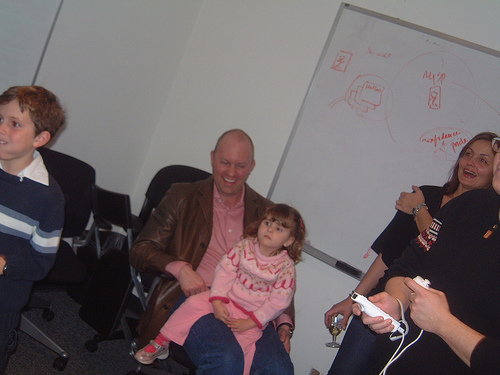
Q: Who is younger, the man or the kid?
A: The kid is younger than the man.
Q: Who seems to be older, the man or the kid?
A: The man is older than the kid.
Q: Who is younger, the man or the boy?
A: The boy is younger than the man.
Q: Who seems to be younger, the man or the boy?
A: The boy is younger than the man.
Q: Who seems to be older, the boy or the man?
A: The man is older than the boy.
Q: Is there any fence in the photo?
A: No, there are no fences.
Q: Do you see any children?
A: Yes, there is a child.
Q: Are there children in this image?
A: Yes, there is a child.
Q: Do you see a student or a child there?
A: Yes, there is a child.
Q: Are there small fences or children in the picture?
A: Yes, there is a small child.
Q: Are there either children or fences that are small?
A: Yes, the child is small.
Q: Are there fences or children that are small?
A: Yes, the child is small.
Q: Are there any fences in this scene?
A: No, there are no fences.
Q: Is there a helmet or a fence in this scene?
A: No, there are no fences or helmets.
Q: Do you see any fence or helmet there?
A: No, there are no fences or helmets.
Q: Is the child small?
A: Yes, the child is small.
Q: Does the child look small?
A: Yes, the child is small.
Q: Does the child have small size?
A: Yes, the child is small.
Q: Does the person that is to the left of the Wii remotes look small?
A: Yes, the child is small.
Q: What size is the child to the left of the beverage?
A: The child is small.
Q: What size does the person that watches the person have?
A: The child has small size.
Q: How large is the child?
A: The child is small.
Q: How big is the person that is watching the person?
A: The child is small.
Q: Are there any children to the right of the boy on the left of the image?
A: Yes, there is a child to the right of the boy.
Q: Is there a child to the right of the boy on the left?
A: Yes, there is a child to the right of the boy.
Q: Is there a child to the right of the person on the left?
A: Yes, there is a child to the right of the boy.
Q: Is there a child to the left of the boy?
A: No, the child is to the right of the boy.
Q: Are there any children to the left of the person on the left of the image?
A: No, the child is to the right of the boy.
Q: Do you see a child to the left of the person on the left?
A: No, the child is to the right of the boy.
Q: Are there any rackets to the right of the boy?
A: No, there is a child to the right of the boy.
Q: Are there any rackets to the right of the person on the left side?
A: No, there is a child to the right of the boy.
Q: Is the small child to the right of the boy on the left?
A: Yes, the kid is to the right of the boy.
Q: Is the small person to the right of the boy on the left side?
A: Yes, the kid is to the right of the boy.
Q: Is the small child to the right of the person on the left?
A: Yes, the kid is to the right of the boy.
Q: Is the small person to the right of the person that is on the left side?
A: Yes, the kid is to the right of the boy.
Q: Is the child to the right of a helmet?
A: No, the child is to the right of the boy.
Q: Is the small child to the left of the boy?
A: No, the child is to the right of the boy.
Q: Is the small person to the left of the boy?
A: No, the child is to the right of the boy.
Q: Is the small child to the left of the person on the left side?
A: No, the child is to the right of the boy.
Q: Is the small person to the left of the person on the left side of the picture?
A: No, the child is to the right of the boy.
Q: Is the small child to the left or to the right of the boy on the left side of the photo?
A: The child is to the right of the boy.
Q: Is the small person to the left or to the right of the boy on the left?
A: The child is to the right of the boy.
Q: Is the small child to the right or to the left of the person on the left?
A: The child is to the right of the boy.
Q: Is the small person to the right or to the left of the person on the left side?
A: The child is to the right of the boy.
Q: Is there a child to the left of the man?
A: Yes, there is a child to the left of the man.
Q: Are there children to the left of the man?
A: Yes, there is a child to the left of the man.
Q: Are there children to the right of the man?
A: No, the child is to the left of the man.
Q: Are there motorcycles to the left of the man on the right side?
A: No, there is a child to the left of the man.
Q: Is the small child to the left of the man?
A: Yes, the child is to the left of the man.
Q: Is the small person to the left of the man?
A: Yes, the child is to the left of the man.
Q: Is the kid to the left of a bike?
A: No, the kid is to the left of the man.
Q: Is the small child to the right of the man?
A: No, the child is to the left of the man.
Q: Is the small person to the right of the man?
A: No, the child is to the left of the man.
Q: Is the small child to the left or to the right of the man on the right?
A: The child is to the left of the man.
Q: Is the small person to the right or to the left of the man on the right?
A: The child is to the left of the man.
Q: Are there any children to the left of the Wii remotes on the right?
A: Yes, there is a child to the left of the Wii remotes.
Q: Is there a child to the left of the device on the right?
A: Yes, there is a child to the left of the Wii remotes.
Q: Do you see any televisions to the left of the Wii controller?
A: No, there is a child to the left of the Wii controller.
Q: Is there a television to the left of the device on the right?
A: No, there is a child to the left of the Wii controller.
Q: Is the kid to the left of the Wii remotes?
A: Yes, the kid is to the left of the Wii remotes.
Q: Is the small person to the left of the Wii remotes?
A: Yes, the kid is to the left of the Wii remotes.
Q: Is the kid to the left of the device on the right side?
A: Yes, the kid is to the left of the Wii remotes.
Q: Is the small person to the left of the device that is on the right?
A: Yes, the kid is to the left of the Wii remotes.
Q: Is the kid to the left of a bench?
A: No, the kid is to the left of the Wii remotes.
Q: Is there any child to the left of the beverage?
A: Yes, there is a child to the left of the beverage.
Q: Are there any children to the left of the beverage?
A: Yes, there is a child to the left of the beverage.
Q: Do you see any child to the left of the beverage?
A: Yes, there is a child to the left of the beverage.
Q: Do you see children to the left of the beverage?
A: Yes, there is a child to the left of the beverage.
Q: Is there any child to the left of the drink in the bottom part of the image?
A: Yes, there is a child to the left of the beverage.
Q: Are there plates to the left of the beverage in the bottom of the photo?
A: No, there is a child to the left of the beverage.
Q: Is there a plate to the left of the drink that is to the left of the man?
A: No, there is a child to the left of the beverage.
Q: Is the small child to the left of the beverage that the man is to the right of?
A: Yes, the kid is to the left of the beverage.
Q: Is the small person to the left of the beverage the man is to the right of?
A: Yes, the kid is to the left of the beverage.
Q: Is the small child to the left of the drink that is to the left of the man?
A: Yes, the kid is to the left of the beverage.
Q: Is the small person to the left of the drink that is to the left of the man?
A: Yes, the kid is to the left of the beverage.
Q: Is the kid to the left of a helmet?
A: No, the kid is to the left of the beverage.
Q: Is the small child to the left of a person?
A: Yes, the child is to the left of a person.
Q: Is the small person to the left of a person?
A: Yes, the child is to the left of a person.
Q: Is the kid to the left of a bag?
A: No, the kid is to the left of a person.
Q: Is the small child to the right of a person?
A: No, the kid is to the left of a person.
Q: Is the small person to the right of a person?
A: No, the kid is to the left of a person.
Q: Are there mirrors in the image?
A: No, there are no mirrors.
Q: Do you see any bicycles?
A: No, there are no bicycles.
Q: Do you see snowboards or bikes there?
A: No, there are no bikes or snowboards.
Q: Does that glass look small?
A: Yes, the glass is small.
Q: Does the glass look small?
A: Yes, the glass is small.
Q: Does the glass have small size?
A: Yes, the glass is small.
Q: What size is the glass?
A: The glass is small.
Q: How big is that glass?
A: The glass is small.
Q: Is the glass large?
A: No, the glass is small.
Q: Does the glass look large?
A: No, the glass is small.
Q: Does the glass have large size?
A: No, the glass is small.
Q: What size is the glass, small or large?
A: The glass is small.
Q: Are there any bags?
A: No, there are no bags.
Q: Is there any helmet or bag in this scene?
A: No, there are no bags or helmets.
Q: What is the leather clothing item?
A: The clothing item is a jacket.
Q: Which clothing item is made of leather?
A: The clothing item is a jacket.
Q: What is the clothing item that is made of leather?
A: The clothing item is a jacket.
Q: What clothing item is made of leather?
A: The clothing item is a jacket.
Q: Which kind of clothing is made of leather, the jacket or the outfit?
A: The jacket is made of leather.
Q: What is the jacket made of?
A: The jacket is made of leather.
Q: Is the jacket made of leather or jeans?
A: The jacket is made of leather.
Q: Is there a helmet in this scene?
A: No, there are no helmets.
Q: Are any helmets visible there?
A: No, there are no helmets.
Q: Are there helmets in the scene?
A: No, there are no helmets.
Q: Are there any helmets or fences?
A: No, there are no helmets or fences.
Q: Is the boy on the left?
A: Yes, the boy is on the left of the image.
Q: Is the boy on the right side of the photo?
A: No, the boy is on the left of the image.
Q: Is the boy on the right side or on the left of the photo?
A: The boy is on the left of the image.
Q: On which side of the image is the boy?
A: The boy is on the left of the image.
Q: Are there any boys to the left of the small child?
A: Yes, there is a boy to the left of the child.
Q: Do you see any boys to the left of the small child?
A: Yes, there is a boy to the left of the child.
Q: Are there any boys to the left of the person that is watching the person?
A: Yes, there is a boy to the left of the child.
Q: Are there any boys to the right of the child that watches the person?
A: No, the boy is to the left of the kid.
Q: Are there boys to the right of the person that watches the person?
A: No, the boy is to the left of the kid.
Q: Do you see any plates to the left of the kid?
A: No, there is a boy to the left of the kid.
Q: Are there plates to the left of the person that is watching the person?
A: No, there is a boy to the left of the kid.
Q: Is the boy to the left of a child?
A: Yes, the boy is to the left of a child.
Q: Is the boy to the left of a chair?
A: No, the boy is to the left of a child.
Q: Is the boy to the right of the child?
A: No, the boy is to the left of the child.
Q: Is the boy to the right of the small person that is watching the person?
A: No, the boy is to the left of the child.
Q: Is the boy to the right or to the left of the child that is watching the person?
A: The boy is to the left of the kid.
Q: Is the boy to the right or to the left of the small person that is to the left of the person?
A: The boy is to the left of the kid.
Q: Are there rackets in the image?
A: No, there are no rackets.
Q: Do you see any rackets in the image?
A: No, there are no rackets.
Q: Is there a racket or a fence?
A: No, there are no rackets or fences.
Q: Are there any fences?
A: No, there are no fences.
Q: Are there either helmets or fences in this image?
A: No, there are no fences or helmets.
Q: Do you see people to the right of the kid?
A: Yes, there is a person to the right of the kid.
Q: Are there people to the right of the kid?
A: Yes, there is a person to the right of the kid.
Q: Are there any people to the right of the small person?
A: Yes, there is a person to the right of the kid.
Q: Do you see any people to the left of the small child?
A: No, the person is to the right of the child.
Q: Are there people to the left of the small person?
A: No, the person is to the right of the child.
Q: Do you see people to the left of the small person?
A: No, the person is to the right of the child.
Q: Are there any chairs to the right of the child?
A: No, there is a person to the right of the child.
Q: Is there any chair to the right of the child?
A: No, there is a person to the right of the child.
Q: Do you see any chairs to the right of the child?
A: No, there is a person to the right of the child.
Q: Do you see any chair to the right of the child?
A: No, there is a person to the right of the child.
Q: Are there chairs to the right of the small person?
A: No, there is a person to the right of the child.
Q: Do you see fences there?
A: No, there are no fences.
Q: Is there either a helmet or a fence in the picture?
A: No, there are no fences or helmets.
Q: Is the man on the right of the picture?
A: Yes, the man is on the right of the image.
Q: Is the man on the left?
A: No, the man is on the right of the image.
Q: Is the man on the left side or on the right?
A: The man is on the right of the image.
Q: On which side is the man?
A: The man is on the right of the image.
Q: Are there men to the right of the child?
A: Yes, there is a man to the right of the child.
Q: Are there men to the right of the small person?
A: Yes, there is a man to the right of the child.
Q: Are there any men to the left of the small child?
A: No, the man is to the right of the child.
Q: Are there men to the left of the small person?
A: No, the man is to the right of the child.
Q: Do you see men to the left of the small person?
A: No, the man is to the right of the child.